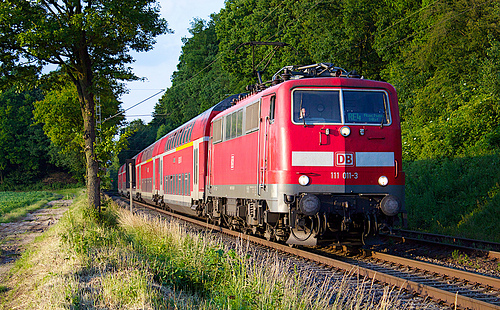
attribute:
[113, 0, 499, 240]
forest — dense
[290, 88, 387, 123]
window — in the picture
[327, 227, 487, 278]
railroad — in the picture